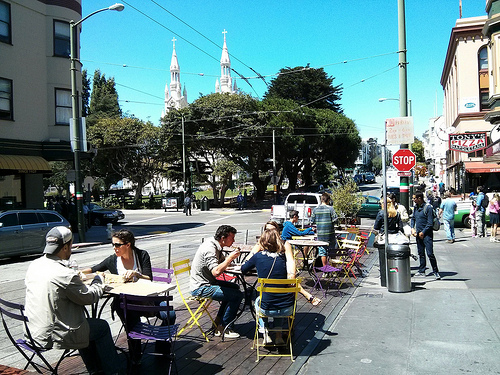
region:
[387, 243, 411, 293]
Aluminum trash container with black trash bag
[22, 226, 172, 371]
Man and woman sitting at a table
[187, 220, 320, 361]
Two women and a man sitting at a table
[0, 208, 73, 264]
Gray car in a parking space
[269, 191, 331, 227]
White truck in a parking space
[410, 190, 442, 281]
Man standing with a backpack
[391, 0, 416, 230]
Red stop sign on a tall street light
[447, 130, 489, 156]
Hanging Tony's Pizza banner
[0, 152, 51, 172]
Tan awning on building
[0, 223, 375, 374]
Four tables and several chairs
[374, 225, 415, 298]
trash cans by sign post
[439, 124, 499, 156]
pizza shop sign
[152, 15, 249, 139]
tall white church towers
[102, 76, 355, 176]
bushy green trees shading sidewalk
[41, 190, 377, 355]
various people eating along street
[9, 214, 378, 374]
oddly colored chairs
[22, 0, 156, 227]
metal utility pole for lamp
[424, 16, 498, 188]
two story building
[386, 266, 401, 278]
sticker on trash can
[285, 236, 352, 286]
only vacant table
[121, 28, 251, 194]
White Christian church with two steeples.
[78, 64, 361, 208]
Trees in a city.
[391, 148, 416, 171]
Stop sign on a city street.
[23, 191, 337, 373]
Persons dining on a city street.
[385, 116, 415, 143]
No parking sign on a city street.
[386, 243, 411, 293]
Trash receptacle on a city street.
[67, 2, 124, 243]
Light post on a city street.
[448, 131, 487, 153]
Sign for a pizza shop.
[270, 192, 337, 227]
White pickup truck on a city street.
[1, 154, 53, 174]
Awning on a building on a city street.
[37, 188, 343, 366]
people sitting along a street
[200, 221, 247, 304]
man eating at a table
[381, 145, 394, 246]
sign on a pole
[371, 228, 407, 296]
trash can on a side walk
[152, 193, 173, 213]
bench on a side walk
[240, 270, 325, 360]
a yellow chair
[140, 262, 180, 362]
a purple chair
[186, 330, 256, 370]
bricks on a side walk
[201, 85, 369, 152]
trees along the street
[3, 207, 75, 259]
car parked on the street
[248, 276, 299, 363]
Bright yellow folding chair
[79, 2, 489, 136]
Cloudless blue sky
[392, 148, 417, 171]
Red stop sign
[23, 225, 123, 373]
Man wearing backward baseball cap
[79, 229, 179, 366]
Woman in black sunglasses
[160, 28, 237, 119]
Two tall spires of a church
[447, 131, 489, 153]
Street sign for a pizza place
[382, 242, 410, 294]
Stainless steel trash container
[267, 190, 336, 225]
Large white pick up truck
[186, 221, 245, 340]
A man with dark hair eating outside